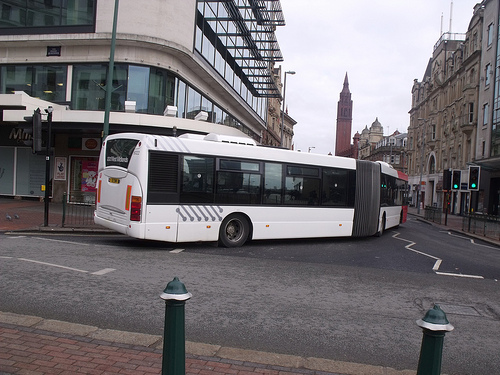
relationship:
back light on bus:
[130, 195, 142, 221] [84, 108, 421, 255]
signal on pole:
[446, 169, 482, 191] [446, 190, 483, 229]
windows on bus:
[146, 150, 357, 210] [108, 125, 420, 277]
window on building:
[456, 98, 497, 133] [408, 51, 486, 196]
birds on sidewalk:
[3, 210, 73, 246] [11, 191, 130, 248]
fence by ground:
[400, 190, 470, 220] [260, 242, 445, 300]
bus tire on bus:
[219, 214, 251, 248] [114, 118, 456, 248]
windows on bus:
[146, 150, 357, 210] [115, 126, 427, 232]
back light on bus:
[130, 195, 142, 221] [109, 136, 378, 231]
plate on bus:
[87, 166, 141, 185] [109, 133, 438, 264]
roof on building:
[351, 115, 396, 136] [348, 103, 408, 158]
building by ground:
[364, 49, 493, 171] [260, 242, 445, 300]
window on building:
[84, 60, 205, 142] [32, 22, 252, 253]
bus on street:
[97, 139, 437, 275] [126, 240, 452, 337]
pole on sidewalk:
[160, 277, 196, 373] [27, 300, 263, 367]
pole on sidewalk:
[93, 1, 120, 129] [0, 193, 110, 234]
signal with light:
[452, 165, 482, 191] [459, 178, 479, 196]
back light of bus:
[125, 191, 146, 223] [92, 122, 410, 252]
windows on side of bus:
[175, 148, 395, 215] [92, 122, 410, 252]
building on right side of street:
[401, 14, 484, 204] [407, 209, 467, 254]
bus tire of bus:
[219, 214, 251, 248] [92, 122, 410, 252]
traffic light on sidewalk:
[28, 101, 56, 228] [0, 200, 105, 234]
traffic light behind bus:
[28, 101, 56, 228] [92, 122, 410, 252]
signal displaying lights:
[452, 165, 482, 191] [449, 180, 478, 189]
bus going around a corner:
[93, 132, 412, 249] [77, 114, 484, 264]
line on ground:
[393, 226, 484, 284] [260, 242, 445, 300]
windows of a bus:
[146, 150, 357, 210] [92, 122, 410, 252]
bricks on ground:
[6, 309, 434, 371] [23, 244, 492, 374]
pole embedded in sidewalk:
[146, 273, 195, 373] [3, 296, 395, 372]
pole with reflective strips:
[160, 277, 196, 373] [151, 285, 458, 339]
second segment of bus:
[85, 123, 360, 256] [91, 116, 422, 249]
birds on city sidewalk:
[3, 212, 14, 220] [4, 187, 104, 232]